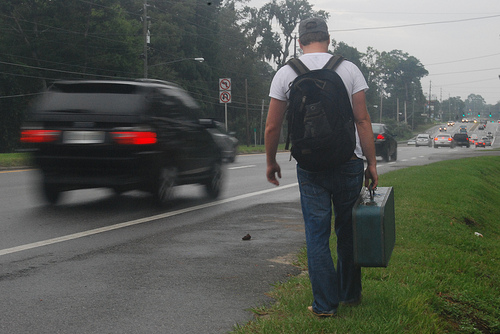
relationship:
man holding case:
[282, 27, 405, 254] [351, 186, 396, 268]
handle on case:
[364, 183, 380, 209] [351, 186, 396, 268]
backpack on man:
[291, 64, 351, 168] [282, 27, 405, 254]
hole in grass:
[446, 198, 481, 231] [319, 147, 500, 310]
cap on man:
[294, 18, 328, 38] [282, 27, 405, 254]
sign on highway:
[209, 71, 240, 109] [10, 139, 450, 193]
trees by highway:
[19, 18, 422, 127] [10, 139, 450, 193]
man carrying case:
[282, 27, 405, 254] [365, 200, 410, 264]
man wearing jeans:
[282, 27, 405, 254] [303, 169, 372, 310]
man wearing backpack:
[282, 27, 405, 254] [291, 64, 351, 168]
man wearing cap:
[282, 27, 405, 254] [294, 14, 350, 32]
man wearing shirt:
[282, 27, 405, 254] [262, 61, 359, 105]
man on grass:
[282, 27, 405, 254] [319, 147, 500, 310]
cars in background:
[428, 123, 500, 161] [355, 97, 499, 163]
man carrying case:
[282, 27, 405, 254] [351, 186, 396, 268]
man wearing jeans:
[282, 27, 405, 254] [297, 157, 365, 314]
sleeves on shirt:
[342, 67, 374, 88] [262, 61, 359, 105]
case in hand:
[351, 186, 396, 268] [364, 164, 378, 190]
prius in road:
[360, 118, 422, 162] [373, 144, 499, 164]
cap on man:
[294, 14, 350, 32] [282, 27, 405, 254]